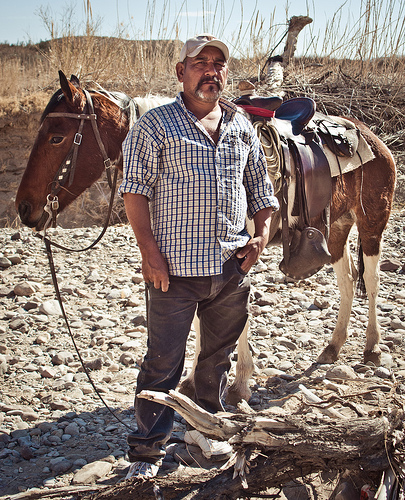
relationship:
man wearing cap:
[118, 36, 280, 483] [181, 34, 228, 59]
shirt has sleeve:
[118, 99, 279, 232] [253, 155, 278, 215]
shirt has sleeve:
[118, 99, 279, 232] [127, 122, 150, 192]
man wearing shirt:
[118, 36, 280, 483] [118, 99, 279, 232]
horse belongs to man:
[14, 69, 402, 405] [166, 107, 242, 405]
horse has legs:
[14, 70, 396, 405] [329, 167, 386, 368]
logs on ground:
[0, 389, 405, 500] [0, 209, 403, 498]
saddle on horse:
[287, 110, 329, 278] [1, 79, 387, 379]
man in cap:
[114, 23, 263, 268] [183, 26, 223, 60]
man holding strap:
[118, 36, 280, 483] [33, 239, 171, 438]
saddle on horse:
[274, 98, 328, 278] [14, 69, 402, 405]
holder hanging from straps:
[289, 243, 329, 277] [271, 116, 371, 273]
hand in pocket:
[238, 237, 265, 271] [223, 257, 253, 280]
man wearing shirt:
[118, 36, 280, 483] [114, 90, 277, 274]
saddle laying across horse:
[274, 98, 328, 278] [10, 14, 402, 387]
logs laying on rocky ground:
[134, 385, 396, 487] [0, 212, 404, 496]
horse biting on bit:
[14, 70, 396, 405] [44, 197, 56, 227]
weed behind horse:
[294, 33, 384, 121] [22, 81, 120, 211]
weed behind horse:
[0, 0, 405, 122] [22, 81, 120, 211]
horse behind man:
[14, 70, 396, 405] [142, 79, 247, 431]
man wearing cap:
[118, 36, 280, 483] [180, 33, 230, 63]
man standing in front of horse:
[118, 36, 280, 483] [14, 69, 402, 405]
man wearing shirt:
[118, 36, 280, 483] [120, 89, 282, 285]